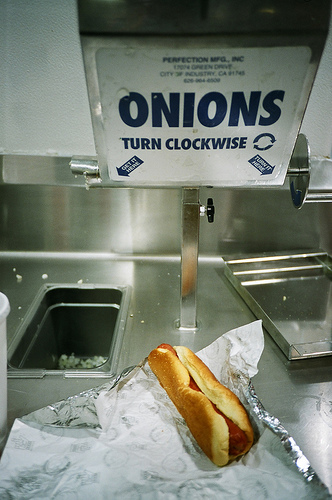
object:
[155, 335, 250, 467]
hotdog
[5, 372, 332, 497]
counter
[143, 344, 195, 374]
bun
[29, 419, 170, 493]
paper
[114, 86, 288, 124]
onion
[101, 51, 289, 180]
sign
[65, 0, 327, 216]
machine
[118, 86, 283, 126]
onions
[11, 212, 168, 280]
stainless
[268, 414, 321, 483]
foil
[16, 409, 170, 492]
wrapper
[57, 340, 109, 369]
onions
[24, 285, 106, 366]
bin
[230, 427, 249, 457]
sausage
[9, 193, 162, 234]
surface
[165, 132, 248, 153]
clockwise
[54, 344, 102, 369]
food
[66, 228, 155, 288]
shining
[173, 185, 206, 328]
pole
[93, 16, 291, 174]
box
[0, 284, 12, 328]
side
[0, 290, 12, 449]
cup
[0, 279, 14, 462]
soda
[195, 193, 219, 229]
dial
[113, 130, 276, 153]
directions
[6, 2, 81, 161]
wall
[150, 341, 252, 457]
bread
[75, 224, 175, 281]
metal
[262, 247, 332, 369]
tray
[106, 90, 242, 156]
text